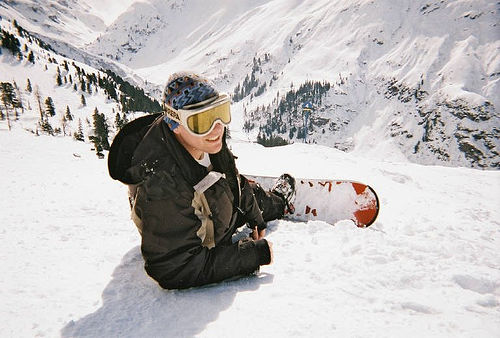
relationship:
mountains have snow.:
[6, 0, 500, 336] [6, 5, 499, 336]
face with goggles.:
[180, 84, 227, 156] [170, 93, 234, 135]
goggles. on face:
[170, 93, 234, 135] [180, 84, 227, 156]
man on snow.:
[108, 73, 294, 287] [6, 5, 499, 336]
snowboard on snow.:
[239, 173, 382, 230] [6, 5, 499, 336]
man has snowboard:
[108, 73, 294, 287] [239, 173, 382, 230]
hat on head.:
[157, 71, 217, 134] [164, 71, 231, 158]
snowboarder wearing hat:
[108, 71, 380, 293] [157, 71, 217, 134]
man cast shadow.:
[108, 73, 294, 287] [48, 245, 272, 337]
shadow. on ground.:
[48, 245, 272, 337] [13, 138, 494, 338]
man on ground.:
[108, 73, 294, 287] [13, 138, 494, 338]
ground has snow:
[13, 138, 494, 338] [6, 5, 499, 336]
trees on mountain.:
[5, 19, 333, 153] [6, 0, 500, 336]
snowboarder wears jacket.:
[108, 71, 380, 293] [113, 120, 273, 280]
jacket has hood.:
[113, 120, 273, 280] [108, 105, 156, 191]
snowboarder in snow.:
[108, 71, 380, 293] [6, 5, 499, 336]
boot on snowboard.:
[271, 173, 299, 222] [239, 173, 382, 230]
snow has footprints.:
[1, 135, 499, 330] [330, 243, 498, 337]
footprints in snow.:
[392, 218, 493, 337] [6, 5, 499, 336]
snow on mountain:
[1, 135, 499, 330] [6, 0, 500, 336]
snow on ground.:
[1, 135, 499, 330] [13, 138, 494, 338]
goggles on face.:
[170, 93, 234, 135] [180, 84, 227, 156]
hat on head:
[157, 71, 217, 134] [164, 71, 231, 158]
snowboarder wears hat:
[108, 71, 380, 293] [157, 71, 217, 134]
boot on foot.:
[271, 173, 299, 222] [266, 170, 299, 230]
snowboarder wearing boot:
[108, 71, 380, 293] [271, 173, 299, 222]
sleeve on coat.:
[151, 178, 273, 284] [108, 73, 294, 287]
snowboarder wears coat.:
[108, 71, 380, 293] [113, 120, 273, 280]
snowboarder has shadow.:
[108, 71, 380, 293] [48, 245, 272, 337]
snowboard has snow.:
[239, 173, 382, 230] [260, 180, 369, 223]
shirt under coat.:
[194, 152, 220, 175] [113, 120, 273, 280]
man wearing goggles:
[108, 73, 294, 287] [170, 93, 234, 135]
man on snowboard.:
[108, 73, 294, 287] [239, 173, 382, 230]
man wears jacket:
[108, 73, 294, 287] [113, 120, 273, 280]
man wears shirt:
[108, 73, 294, 287] [194, 152, 220, 175]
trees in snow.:
[5, 19, 333, 153] [6, 5, 499, 336]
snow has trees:
[1, 135, 499, 330] [5, 19, 333, 153]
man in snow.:
[108, 73, 294, 287] [6, 5, 499, 336]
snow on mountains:
[1, 135, 499, 330] [6, 0, 500, 336]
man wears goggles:
[108, 73, 294, 287] [170, 93, 234, 135]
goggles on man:
[170, 93, 234, 135] [108, 73, 294, 287]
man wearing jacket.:
[108, 73, 294, 287] [113, 120, 273, 280]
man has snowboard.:
[108, 73, 294, 287] [239, 173, 382, 230]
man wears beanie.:
[108, 73, 294, 287] [157, 71, 217, 134]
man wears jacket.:
[108, 73, 294, 287] [113, 120, 273, 280]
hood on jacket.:
[108, 105, 156, 191] [113, 120, 273, 280]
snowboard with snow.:
[239, 173, 382, 230] [260, 180, 369, 223]